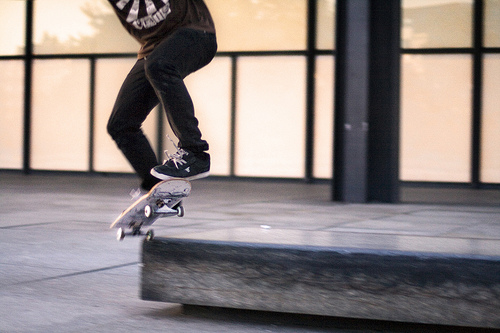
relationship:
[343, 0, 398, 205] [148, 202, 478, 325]
steel behind concrete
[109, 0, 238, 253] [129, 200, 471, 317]
skateboarder on concrete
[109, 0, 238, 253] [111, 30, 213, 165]
skateboarder in black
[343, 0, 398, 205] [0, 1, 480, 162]
pole next building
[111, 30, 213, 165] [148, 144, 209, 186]
black shoe foot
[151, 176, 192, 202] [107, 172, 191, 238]
front of board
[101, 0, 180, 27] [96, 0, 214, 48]
writing on shirt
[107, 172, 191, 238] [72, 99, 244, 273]
skateboard in air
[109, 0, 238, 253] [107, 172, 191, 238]
person on skateboard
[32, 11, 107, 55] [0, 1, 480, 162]
trees in background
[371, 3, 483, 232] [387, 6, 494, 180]
reflection of window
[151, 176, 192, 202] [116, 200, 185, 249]
front of wheels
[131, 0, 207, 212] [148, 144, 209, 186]
person wearing shoes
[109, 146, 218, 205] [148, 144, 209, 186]
wearing black shoes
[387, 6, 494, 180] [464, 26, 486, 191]
pink window bar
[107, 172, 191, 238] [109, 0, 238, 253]
skateboarde goes airborne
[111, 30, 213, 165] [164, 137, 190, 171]
black sneaker laces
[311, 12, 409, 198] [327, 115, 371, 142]
steel girder rivets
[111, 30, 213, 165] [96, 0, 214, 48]
black shirt design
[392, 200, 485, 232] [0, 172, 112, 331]
concrete section flooring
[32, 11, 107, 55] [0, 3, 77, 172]
trees show windows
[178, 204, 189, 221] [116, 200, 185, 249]
white skateboard wheels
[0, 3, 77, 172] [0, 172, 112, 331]
opaque windows floor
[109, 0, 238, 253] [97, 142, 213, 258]
one person skating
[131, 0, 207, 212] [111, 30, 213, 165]
person black pants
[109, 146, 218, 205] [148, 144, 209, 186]
sneakers black color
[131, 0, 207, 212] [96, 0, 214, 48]
person wearing shirt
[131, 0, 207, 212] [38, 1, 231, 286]
person doing trick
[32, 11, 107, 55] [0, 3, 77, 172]
trees in window